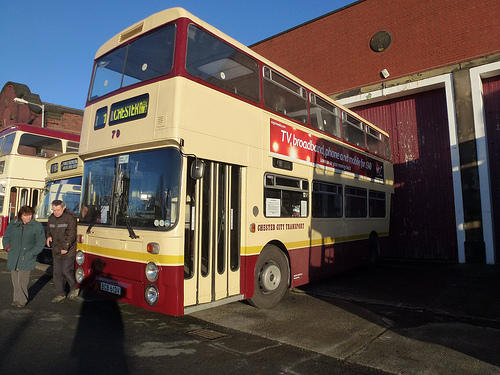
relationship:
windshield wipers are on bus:
[82, 205, 143, 244] [74, 5, 396, 318]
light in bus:
[72, 251, 87, 268] [65, 27, 407, 337]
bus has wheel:
[74, 5, 396, 318] [247, 242, 292, 310]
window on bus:
[258, 63, 317, 128] [74, 5, 396, 318]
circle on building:
[366, 26, 394, 58] [288, 10, 496, 275]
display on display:
[102, 99, 146, 123] [102, 99, 146, 123]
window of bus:
[260, 173, 313, 220] [82, 21, 397, 303]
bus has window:
[74, 5, 396, 318] [256, 182, 305, 223]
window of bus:
[83, 143, 182, 233] [74, 5, 396, 318]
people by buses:
[0, 197, 95, 324] [3, 8, 459, 346]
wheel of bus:
[252, 242, 295, 306] [74, 5, 396, 318]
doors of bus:
[134, 130, 296, 337] [74, 5, 396, 318]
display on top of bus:
[94, 99, 149, 124] [74, 5, 396, 318]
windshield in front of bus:
[77, 24, 191, 96] [52, 12, 408, 330]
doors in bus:
[182, 152, 242, 311] [74, 5, 396, 318]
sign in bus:
[253, 111, 403, 186] [74, 5, 396, 318]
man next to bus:
[43, 196, 83, 303] [74, 5, 396, 318]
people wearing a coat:
[1, 204, 46, 310] [6, 215, 43, 280]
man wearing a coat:
[43, 196, 83, 303] [45, 209, 77, 256]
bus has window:
[74, 5, 396, 318] [74, 154, 120, 229]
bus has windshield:
[74, 5, 396, 318] [71, 16, 191, 110]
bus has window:
[74, 5, 396, 318] [261, 167, 315, 223]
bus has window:
[74, 5, 396, 318] [185, 19, 264, 104]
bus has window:
[74, 5, 396, 318] [186, 25, 262, 103]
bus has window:
[74, 5, 396, 318] [301, 81, 341, 133]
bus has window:
[165, 72, 301, 232] [304, 177, 344, 221]